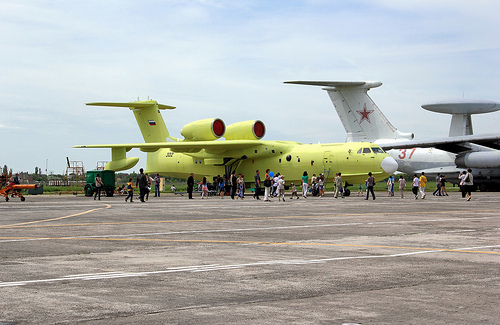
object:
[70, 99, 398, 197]
plane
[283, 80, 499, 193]
plane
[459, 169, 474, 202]
person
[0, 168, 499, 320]
airport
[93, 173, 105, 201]
people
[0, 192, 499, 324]
tarmac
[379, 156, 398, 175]
nose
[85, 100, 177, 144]
tail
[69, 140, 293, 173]
wing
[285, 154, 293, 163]
windows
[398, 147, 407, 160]
number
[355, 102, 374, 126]
star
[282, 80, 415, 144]
tail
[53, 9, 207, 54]
clouds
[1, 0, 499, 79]
sky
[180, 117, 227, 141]
engines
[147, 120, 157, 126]
flag